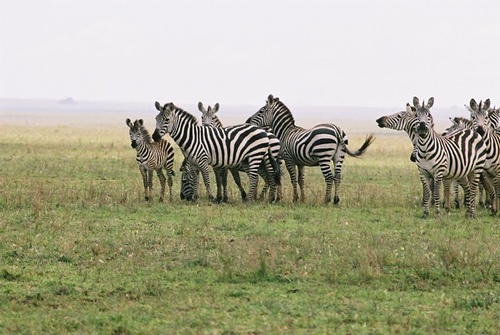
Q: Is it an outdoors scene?
A: Yes, it is outdoors.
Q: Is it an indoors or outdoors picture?
A: It is outdoors.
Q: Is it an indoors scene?
A: No, it is outdoors.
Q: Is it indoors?
A: No, it is outdoors.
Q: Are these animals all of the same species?
A: Yes, all the animals are zebras.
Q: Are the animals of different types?
A: No, all the animals are zebras.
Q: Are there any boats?
A: No, there are no boats.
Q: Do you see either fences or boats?
A: No, there are no boats or fences.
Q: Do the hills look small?
A: Yes, the hills are small.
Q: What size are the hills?
A: The hills are small.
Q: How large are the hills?
A: The hills are small.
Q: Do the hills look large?
A: No, the hills are small.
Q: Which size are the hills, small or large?
A: The hills are small.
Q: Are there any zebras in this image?
A: Yes, there is a zebra.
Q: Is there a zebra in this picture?
A: Yes, there is a zebra.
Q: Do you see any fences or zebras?
A: Yes, there is a zebra.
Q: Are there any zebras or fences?
A: Yes, there is a zebra.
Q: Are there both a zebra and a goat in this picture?
A: No, there is a zebra but no goats.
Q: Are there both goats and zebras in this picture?
A: No, there is a zebra but no goats.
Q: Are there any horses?
A: No, there are no horses.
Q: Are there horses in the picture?
A: No, there are no horses.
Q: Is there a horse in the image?
A: No, there are no horses.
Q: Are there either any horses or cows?
A: No, there are no horses or cows.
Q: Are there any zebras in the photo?
A: Yes, there is a zebra.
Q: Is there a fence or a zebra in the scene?
A: Yes, there is a zebra.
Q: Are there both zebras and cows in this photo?
A: No, there is a zebra but no cows.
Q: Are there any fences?
A: No, there are no fences.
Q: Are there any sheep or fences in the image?
A: No, there are no fences or sheep.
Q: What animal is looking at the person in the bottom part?
A: The zebra is looking at the photographer.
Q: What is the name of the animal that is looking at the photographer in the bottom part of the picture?
A: The animal is a zebra.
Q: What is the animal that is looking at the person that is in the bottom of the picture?
A: The animal is a zebra.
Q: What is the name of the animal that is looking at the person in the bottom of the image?
A: The animal is a zebra.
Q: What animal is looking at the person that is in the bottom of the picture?
A: The animal is a zebra.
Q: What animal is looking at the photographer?
A: The animal is a zebra.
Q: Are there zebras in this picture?
A: Yes, there is a zebra.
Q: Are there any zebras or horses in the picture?
A: Yes, there is a zebra.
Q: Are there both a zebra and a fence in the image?
A: No, there is a zebra but no fences.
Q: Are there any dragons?
A: No, there are no dragons.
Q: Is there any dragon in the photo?
A: No, there are no dragons.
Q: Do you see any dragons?
A: No, there are no dragons.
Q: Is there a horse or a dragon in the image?
A: No, there are no dragons or horses.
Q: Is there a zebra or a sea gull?
A: Yes, there is a zebra.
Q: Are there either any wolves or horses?
A: No, there are no horses or wolves.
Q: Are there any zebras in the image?
A: Yes, there is a zebra.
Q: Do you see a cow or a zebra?
A: Yes, there is a zebra.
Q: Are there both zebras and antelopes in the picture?
A: No, there is a zebra but no antelopes.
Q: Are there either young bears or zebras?
A: Yes, there is a young zebra.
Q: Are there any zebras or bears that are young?
A: Yes, the zebra is young.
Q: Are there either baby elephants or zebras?
A: Yes, there is a baby zebra.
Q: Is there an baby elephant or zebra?
A: Yes, there is a baby zebra.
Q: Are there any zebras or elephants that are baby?
A: Yes, the zebra is a baby.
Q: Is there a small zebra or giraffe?
A: Yes, there is a small zebra.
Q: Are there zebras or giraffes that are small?
A: Yes, the zebra is small.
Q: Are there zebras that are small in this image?
A: Yes, there is a small zebra.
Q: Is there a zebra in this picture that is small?
A: Yes, there is a zebra that is small.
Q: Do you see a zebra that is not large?
A: Yes, there is a small zebra.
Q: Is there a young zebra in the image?
A: Yes, there is a young zebra.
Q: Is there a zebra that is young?
A: Yes, there is a zebra that is young.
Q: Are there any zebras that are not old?
A: Yes, there is an young zebra.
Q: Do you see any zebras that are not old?
A: Yes, there is an young zebra.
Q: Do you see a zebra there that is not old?
A: Yes, there is an young zebra.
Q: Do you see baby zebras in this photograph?
A: Yes, there is a baby zebra.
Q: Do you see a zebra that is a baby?
A: Yes, there is a zebra that is a baby.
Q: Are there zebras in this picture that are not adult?
A: Yes, there is an baby zebra.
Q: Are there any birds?
A: No, there are no birds.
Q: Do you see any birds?
A: No, there are no birds.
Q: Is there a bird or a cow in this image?
A: No, there are no birds or cows.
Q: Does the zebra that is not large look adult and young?
A: No, the zebra is young but baby.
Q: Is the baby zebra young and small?
A: Yes, the zebra is young and small.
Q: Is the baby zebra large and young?
A: No, the zebra is young but small.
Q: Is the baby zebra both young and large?
A: No, the zebra is young but small.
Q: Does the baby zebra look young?
A: Yes, the zebra is young.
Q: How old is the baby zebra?
A: The zebra is young.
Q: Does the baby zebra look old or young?
A: The zebra is young.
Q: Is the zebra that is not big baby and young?
A: Yes, the zebra is a baby and young.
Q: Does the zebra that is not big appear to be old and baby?
A: No, the zebra is a baby but young.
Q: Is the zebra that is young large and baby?
A: No, the zebra is a baby but small.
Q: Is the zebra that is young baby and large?
A: No, the zebra is a baby but small.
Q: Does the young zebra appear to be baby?
A: Yes, the zebra is a baby.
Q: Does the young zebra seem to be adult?
A: No, the zebra is a baby.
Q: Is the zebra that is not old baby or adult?
A: The zebra is a baby.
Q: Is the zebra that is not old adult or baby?
A: The zebra is a baby.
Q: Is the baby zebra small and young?
A: Yes, the zebra is small and young.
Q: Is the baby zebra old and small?
A: No, the zebra is small but young.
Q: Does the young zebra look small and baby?
A: Yes, the zebra is small and baby.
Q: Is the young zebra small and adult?
A: No, the zebra is small but baby.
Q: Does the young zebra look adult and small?
A: No, the zebra is small but baby.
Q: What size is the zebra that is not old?
A: The zebra is small.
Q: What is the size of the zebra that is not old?
A: The zebra is small.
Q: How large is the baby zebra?
A: The zebra is small.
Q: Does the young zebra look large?
A: No, the zebra is small.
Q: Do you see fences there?
A: No, there are no fences.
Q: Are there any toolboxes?
A: No, there are no toolboxes.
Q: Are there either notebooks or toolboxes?
A: No, there are no toolboxes or notebooks.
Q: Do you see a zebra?
A: Yes, there is a zebra.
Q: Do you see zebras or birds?
A: Yes, there is a zebra.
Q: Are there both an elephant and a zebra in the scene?
A: No, there is a zebra but no elephants.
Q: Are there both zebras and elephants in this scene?
A: No, there is a zebra but no elephants.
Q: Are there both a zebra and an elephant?
A: No, there is a zebra but no elephants.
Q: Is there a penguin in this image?
A: No, there are no penguins.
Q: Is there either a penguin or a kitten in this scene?
A: No, there are no penguins or kittens.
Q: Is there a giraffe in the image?
A: No, there are no giraffes.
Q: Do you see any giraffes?
A: No, there are no giraffes.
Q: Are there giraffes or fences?
A: No, there are no giraffes or fences.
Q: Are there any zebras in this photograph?
A: Yes, there is a zebra.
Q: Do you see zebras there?
A: Yes, there is a zebra.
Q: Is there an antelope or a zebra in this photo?
A: Yes, there is a zebra.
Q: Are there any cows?
A: No, there are no cows.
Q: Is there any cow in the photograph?
A: No, there are no cows.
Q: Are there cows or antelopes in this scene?
A: No, there are no cows or antelopes.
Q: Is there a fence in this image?
A: No, there are no fences.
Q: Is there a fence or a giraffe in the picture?
A: No, there are no fences or giraffes.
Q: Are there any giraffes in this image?
A: No, there are no giraffes.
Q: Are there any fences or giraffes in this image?
A: No, there are no giraffes or fences.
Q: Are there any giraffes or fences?
A: No, there are no giraffes or fences.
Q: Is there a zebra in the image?
A: Yes, there is a zebra.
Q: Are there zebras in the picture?
A: Yes, there is a zebra.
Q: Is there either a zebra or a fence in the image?
A: Yes, there is a zebra.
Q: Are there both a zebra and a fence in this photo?
A: No, there is a zebra but no fences.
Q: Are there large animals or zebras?
A: Yes, there is a large zebra.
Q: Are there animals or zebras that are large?
A: Yes, the zebra is large.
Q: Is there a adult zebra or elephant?
A: Yes, there is an adult zebra.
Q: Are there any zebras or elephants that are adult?
A: Yes, the zebra is adult.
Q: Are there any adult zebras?
A: Yes, there is an adult zebra.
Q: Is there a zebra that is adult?
A: Yes, there is a zebra that is adult.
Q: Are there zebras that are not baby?
A: Yes, there is a adult zebra.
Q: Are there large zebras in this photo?
A: Yes, there is a large zebra.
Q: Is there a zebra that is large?
A: Yes, there is a zebra that is large.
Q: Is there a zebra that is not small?
A: Yes, there is a large zebra.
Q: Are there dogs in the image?
A: No, there are no dogs.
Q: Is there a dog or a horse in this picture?
A: No, there are no dogs or horses.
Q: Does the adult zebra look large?
A: Yes, the zebra is large.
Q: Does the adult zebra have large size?
A: Yes, the zebra is large.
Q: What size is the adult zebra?
A: The zebra is large.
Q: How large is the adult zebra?
A: The zebra is large.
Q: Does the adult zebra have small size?
A: No, the zebra is large.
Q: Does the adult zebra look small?
A: No, the zebra is large.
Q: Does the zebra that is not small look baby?
A: No, the zebra is adult.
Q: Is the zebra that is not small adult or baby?
A: The zebra is adult.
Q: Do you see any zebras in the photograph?
A: Yes, there is a zebra.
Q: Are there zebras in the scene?
A: Yes, there is a zebra.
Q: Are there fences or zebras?
A: Yes, there is a zebra.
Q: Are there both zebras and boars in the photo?
A: No, there is a zebra but no boars.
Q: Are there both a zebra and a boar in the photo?
A: No, there is a zebra but no boars.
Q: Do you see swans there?
A: No, there are no swans.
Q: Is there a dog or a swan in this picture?
A: No, there are no swans or dogs.